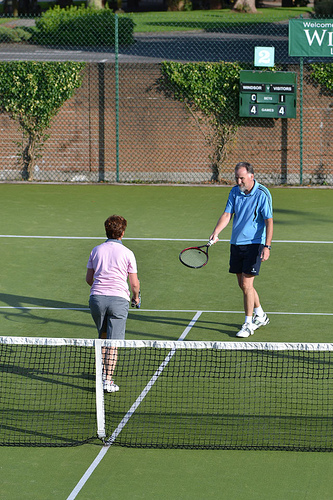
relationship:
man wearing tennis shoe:
[210, 163, 273, 338] [234, 322, 255, 337]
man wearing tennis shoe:
[210, 163, 273, 338] [253, 312, 271, 327]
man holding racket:
[210, 163, 273, 338] [176, 236, 218, 267]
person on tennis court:
[84, 215, 139, 392] [0, 178, 330, 495]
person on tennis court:
[201, 154, 277, 340] [0, 178, 330, 495]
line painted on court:
[134, 219, 214, 251] [23, 183, 324, 350]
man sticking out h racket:
[210, 163, 273, 338] [176, 234, 225, 268]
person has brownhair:
[84, 215, 139, 392] [102, 210, 130, 241]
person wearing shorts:
[84, 215, 139, 392] [88, 296, 129, 340]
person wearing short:
[208, 160, 273, 337] [229, 244, 264, 275]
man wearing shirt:
[210, 163, 273, 338] [225, 183, 273, 250]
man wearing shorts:
[210, 163, 273, 338] [231, 236, 272, 267]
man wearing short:
[210, 163, 273, 338] [229, 244, 264, 275]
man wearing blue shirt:
[217, 153, 296, 339] [223, 190, 271, 245]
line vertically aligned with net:
[91, 337, 108, 437] [0, 327, 331, 454]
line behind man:
[270, 306, 328, 322] [210, 163, 273, 338]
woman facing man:
[83, 215, 139, 392] [210, 163, 273, 338]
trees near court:
[2, 60, 79, 184] [0, 182, 332, 497]